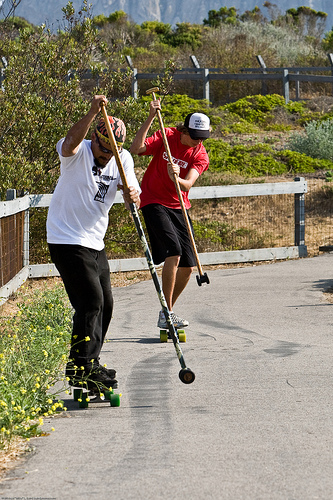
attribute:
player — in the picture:
[52, 106, 190, 236]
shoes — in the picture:
[153, 309, 193, 331]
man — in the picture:
[45, 93, 141, 387]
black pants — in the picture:
[47, 243, 115, 381]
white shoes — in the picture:
[154, 313, 175, 325]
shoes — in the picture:
[61, 355, 119, 394]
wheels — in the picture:
[72, 391, 122, 407]